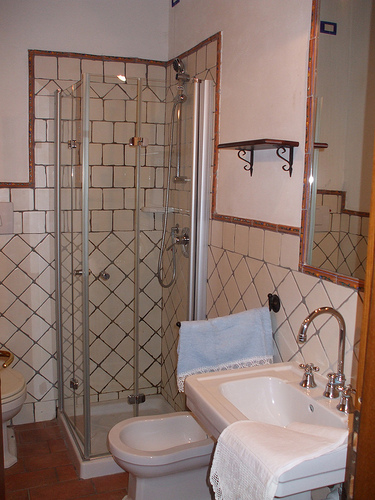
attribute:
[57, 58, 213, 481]
shower — walk-in, glass, small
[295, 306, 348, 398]
faucet — metal, silver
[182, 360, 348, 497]
sink — white, clean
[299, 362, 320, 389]
handle — silver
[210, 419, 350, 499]
towel — white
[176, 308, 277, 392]
towel — light blue, blue, white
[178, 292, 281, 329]
rack — black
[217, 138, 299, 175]
shelf — brown, black, small, empty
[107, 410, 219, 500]
bidet — white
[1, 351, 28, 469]
toilet — white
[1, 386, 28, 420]
bowl — white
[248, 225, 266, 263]
tile — square, white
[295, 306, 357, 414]
fixtures — silver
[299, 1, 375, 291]
mirror — brown, big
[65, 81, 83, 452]
doors — glass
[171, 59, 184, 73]
showerhead — silver, adjustable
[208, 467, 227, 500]
trim — lace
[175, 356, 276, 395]
trim — lace, white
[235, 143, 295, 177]
supports — s shaped, wrought iron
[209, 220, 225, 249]
tile — off-white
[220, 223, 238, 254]
tile — off-white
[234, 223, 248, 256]
tile — off-white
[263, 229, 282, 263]
tile — off-white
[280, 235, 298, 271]
tile — off-white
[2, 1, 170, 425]
wall — tile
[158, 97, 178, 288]
shower hose — metal, grey